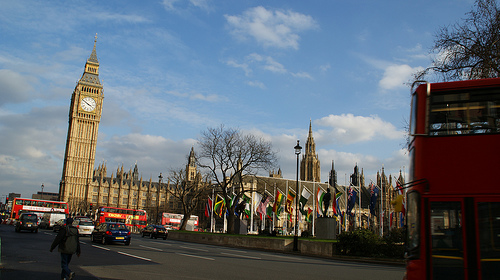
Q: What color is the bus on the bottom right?
A: Red.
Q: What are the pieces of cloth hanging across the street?
A: Flags.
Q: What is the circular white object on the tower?
A: Clock.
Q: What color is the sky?
A: Blue.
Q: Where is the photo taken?
A: Street.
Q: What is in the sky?
A: Clouds.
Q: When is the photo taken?
A: Daytime.